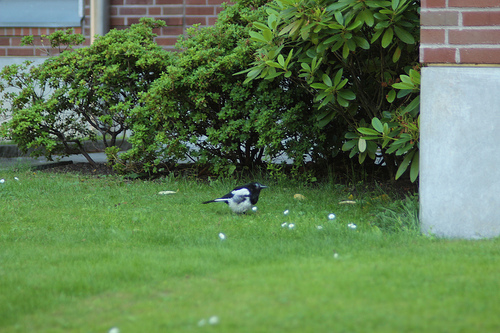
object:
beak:
[260, 185, 268, 189]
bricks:
[458, 48, 499, 65]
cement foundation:
[6, 68, 497, 240]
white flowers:
[217, 232, 225, 240]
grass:
[0, 162, 500, 333]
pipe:
[88, 1, 111, 45]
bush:
[1, 17, 162, 172]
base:
[419, 65, 499, 240]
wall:
[421, 2, 500, 238]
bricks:
[417, 3, 496, 65]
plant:
[364, 0, 420, 184]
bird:
[202, 181, 267, 217]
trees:
[123, 0, 269, 171]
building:
[0, 0, 500, 241]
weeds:
[311, 216, 315, 220]